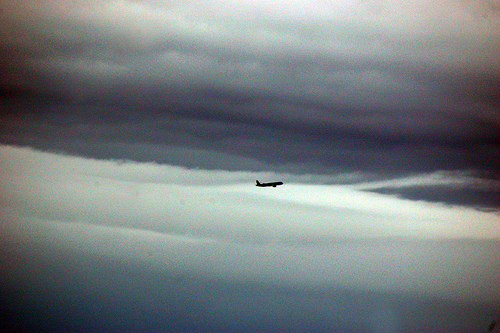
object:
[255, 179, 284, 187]
plane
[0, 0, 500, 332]
sky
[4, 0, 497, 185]
clouds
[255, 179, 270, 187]
back part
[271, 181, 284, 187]
front part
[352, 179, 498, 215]
cloud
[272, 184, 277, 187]
wing